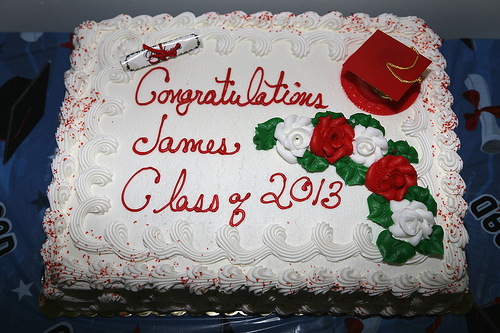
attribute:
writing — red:
[123, 68, 354, 218]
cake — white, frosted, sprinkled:
[41, 19, 476, 310]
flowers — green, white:
[251, 105, 447, 267]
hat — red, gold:
[330, 26, 429, 142]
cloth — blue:
[1, 28, 500, 298]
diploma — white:
[116, 31, 210, 75]